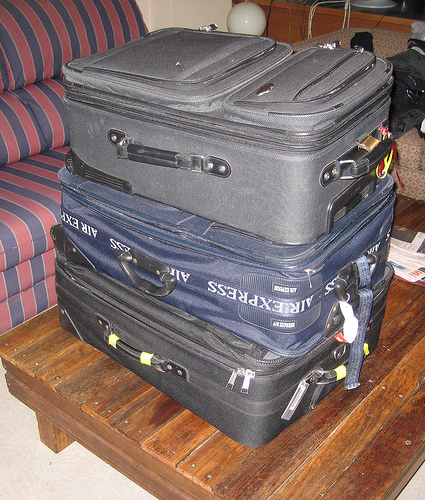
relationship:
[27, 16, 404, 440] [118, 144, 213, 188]
suitcase has handle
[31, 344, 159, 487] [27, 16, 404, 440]
table under bag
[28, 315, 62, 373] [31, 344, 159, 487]
line on table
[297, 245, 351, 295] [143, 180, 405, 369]
zipper on bag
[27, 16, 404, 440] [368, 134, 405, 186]
suitcase has word